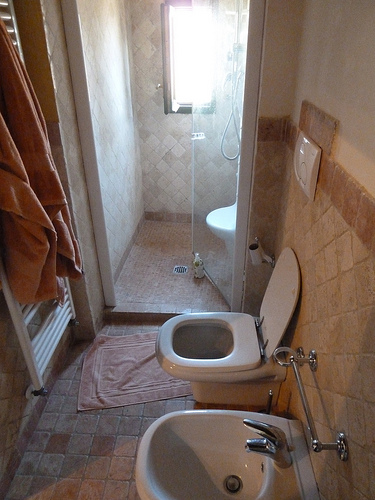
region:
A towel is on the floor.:
[75, 324, 190, 407]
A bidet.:
[137, 405, 302, 495]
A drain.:
[211, 468, 244, 492]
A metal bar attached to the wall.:
[285, 345, 345, 466]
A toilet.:
[154, 244, 296, 403]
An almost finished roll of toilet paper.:
[240, 229, 271, 268]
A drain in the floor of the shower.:
[165, 255, 189, 280]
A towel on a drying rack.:
[0, 0, 102, 390]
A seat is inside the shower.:
[199, 183, 233, 274]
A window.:
[156, 4, 218, 119]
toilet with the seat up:
[150, 238, 324, 389]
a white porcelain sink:
[126, 400, 307, 498]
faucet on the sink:
[235, 414, 295, 472]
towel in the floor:
[69, 312, 205, 418]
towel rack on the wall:
[276, 333, 351, 465]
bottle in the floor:
[186, 250, 208, 292]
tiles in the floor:
[28, 416, 136, 493]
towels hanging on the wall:
[0, 11, 90, 307]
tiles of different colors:
[64, 413, 121, 461]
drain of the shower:
[155, 255, 191, 296]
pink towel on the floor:
[82, 332, 195, 402]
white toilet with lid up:
[166, 246, 294, 402]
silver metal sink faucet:
[241, 417, 288, 462]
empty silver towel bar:
[281, 347, 341, 454]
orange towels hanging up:
[1, 14, 80, 287]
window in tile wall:
[163, 10, 214, 114]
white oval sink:
[132, 413, 283, 498]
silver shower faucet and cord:
[222, 3, 241, 160]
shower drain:
[173, 265, 186, 274]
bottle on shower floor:
[194, 252, 204, 280]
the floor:
[62, 437, 92, 491]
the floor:
[45, 458, 75, 494]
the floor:
[74, 417, 97, 464]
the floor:
[8, 464, 78, 491]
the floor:
[19, 422, 65, 490]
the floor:
[58, 451, 106, 494]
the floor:
[1, 407, 68, 455]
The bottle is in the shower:
[187, 253, 210, 282]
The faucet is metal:
[219, 386, 313, 496]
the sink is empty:
[144, 410, 252, 492]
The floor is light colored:
[39, 410, 116, 490]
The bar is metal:
[289, 364, 362, 481]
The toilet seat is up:
[154, 308, 273, 389]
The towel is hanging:
[2, 123, 101, 328]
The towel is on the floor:
[97, 313, 222, 418]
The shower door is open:
[168, 133, 268, 330]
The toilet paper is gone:
[243, 232, 300, 284]